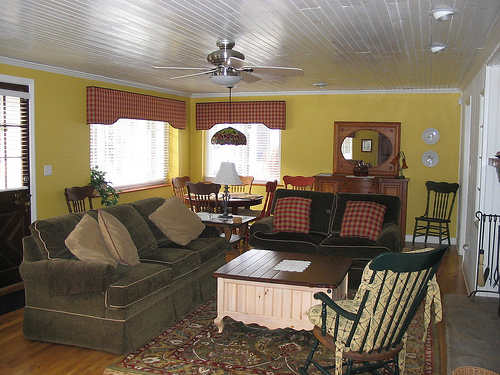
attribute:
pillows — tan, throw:
[57, 211, 147, 281]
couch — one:
[23, 178, 243, 353]